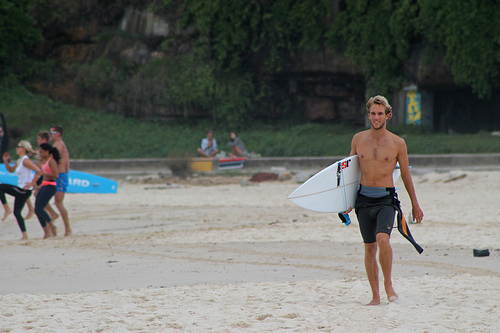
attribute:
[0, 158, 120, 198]
surfboard — light blue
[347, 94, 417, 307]
man — carrying, walking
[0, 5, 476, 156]
landscape — lush, rocky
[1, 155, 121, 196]
surfboard — light blue, white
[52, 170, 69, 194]
shorts — blue, pair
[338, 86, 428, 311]
man — white 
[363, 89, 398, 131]
hair — blonde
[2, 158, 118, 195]
surfboard — blue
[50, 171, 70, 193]
trunks — blue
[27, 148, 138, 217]
surfboard — long, light blue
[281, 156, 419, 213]
board — white, surf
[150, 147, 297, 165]
area — grassy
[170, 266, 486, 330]
beach — sandy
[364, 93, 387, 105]
hair — short 